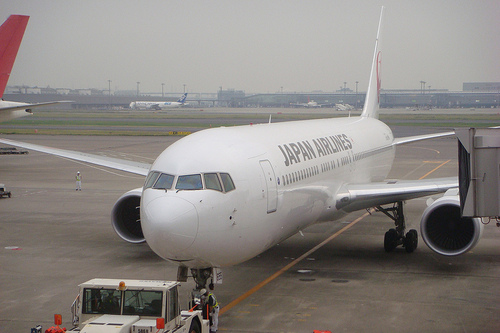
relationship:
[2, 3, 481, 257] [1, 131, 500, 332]
plane on top of tarmack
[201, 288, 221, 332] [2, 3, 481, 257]
guy near plane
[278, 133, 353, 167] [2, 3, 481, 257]
words on a plane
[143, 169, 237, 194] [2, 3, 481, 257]
windshield of plane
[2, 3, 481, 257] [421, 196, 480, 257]
plane with engine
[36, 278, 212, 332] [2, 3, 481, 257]
car near plane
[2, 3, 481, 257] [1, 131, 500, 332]
plane on tarmack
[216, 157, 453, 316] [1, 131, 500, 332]
line on tarmack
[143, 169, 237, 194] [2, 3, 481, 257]
windshield on a plane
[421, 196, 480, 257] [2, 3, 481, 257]
engine on a plane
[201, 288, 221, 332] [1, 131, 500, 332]
guy on tarmack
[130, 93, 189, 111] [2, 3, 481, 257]
plane behind plane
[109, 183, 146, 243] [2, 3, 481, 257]
engine on a plane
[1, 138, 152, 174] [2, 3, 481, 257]
wing of a plane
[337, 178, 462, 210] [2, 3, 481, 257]
wing of a plane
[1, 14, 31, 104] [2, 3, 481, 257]
tail of a plane